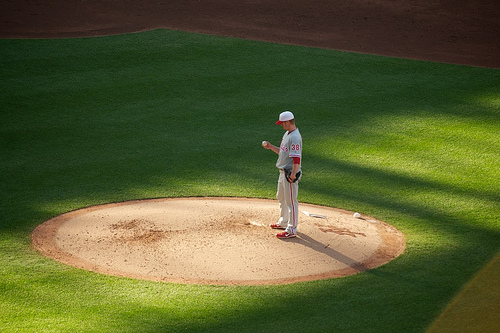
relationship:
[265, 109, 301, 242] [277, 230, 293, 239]
player wearing shoe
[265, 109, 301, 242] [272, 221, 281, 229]
player wearing shoe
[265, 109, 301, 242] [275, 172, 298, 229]
player wearing pants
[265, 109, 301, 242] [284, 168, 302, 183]
player wearing glove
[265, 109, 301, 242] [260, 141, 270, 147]
player holding ball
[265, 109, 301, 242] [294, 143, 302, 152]
player has number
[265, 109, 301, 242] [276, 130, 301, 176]
player wearing shirt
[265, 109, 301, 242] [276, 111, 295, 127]
player wearing hat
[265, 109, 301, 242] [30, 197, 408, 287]
player standing on mound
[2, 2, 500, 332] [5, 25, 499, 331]
shadow on grass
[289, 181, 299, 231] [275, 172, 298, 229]
stripe on pants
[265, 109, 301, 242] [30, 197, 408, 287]
player on mound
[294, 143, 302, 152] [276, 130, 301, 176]
number on shirt